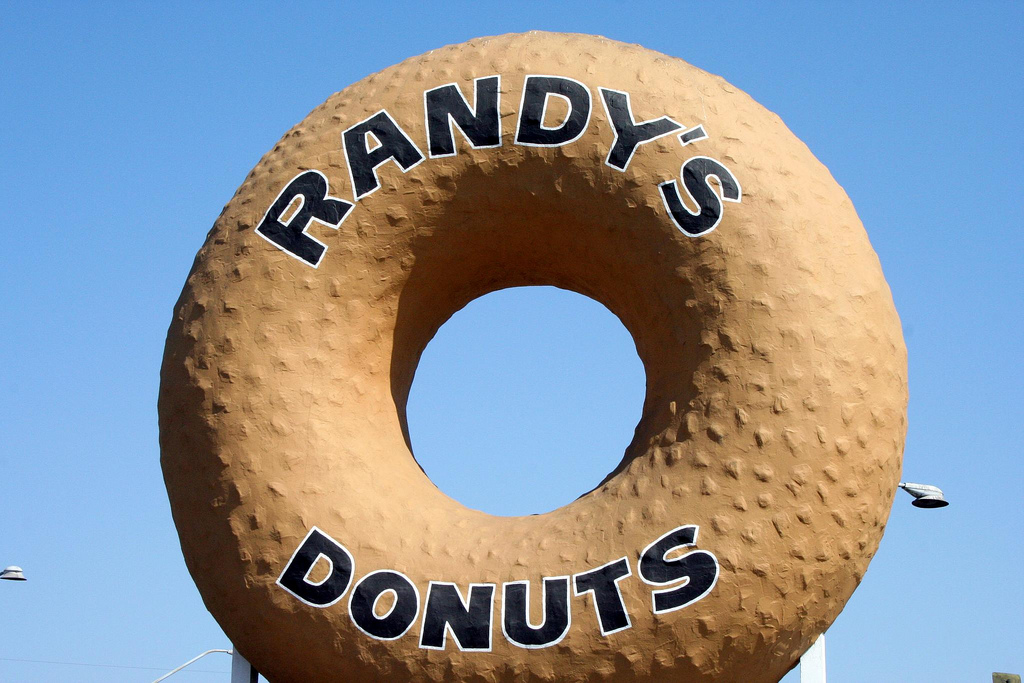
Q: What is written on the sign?
A: Randy's Donuts.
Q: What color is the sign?
A: Tan.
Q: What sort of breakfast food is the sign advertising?
A: Donuts.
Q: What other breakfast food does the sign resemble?
A: Bagels.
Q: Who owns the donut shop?
A: Randy.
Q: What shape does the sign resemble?
A: Circle.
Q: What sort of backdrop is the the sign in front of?
A: The sky.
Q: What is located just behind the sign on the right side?
A: A streetlight.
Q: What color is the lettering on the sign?
A: Black.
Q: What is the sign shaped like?
A: A donut.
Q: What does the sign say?
A: Randy's Donuts.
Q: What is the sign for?
A: A donut shop.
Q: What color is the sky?
A: Blue.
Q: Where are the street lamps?
A: Behind the donut sign.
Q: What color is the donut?
A: Brown.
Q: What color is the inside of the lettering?
A: Black.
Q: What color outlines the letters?
A: White.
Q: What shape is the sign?
A: A circle.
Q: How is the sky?
A: Cloudless.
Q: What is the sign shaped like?
A: A doughnut.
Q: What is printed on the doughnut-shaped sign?
A: "RANDY'S DONUTS".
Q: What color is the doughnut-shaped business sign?
A: Brown.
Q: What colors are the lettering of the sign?
A: Black and white.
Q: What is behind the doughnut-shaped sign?
A: Street lights.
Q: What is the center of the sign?
A: A hole.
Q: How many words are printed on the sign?
A: Two.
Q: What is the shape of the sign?
A: Doughnut.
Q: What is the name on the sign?
A: Randys donuts.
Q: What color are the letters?
A: Black.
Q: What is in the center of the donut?
A: A hole.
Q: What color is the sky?
A: Blue.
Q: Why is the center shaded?
A: Shadow.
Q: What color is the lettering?
A: Black and white.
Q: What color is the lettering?
A: Black and white.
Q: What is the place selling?
A: Donuts.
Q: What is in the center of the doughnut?
A: A doughnut hole.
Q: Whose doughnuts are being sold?
A: Randy's.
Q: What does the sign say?
A: Randy's donuts.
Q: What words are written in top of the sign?
A: Randy's.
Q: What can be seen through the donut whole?
A: The sky.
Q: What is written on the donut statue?
A: Randy's Donuts.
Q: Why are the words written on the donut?
A: To advertise the shop.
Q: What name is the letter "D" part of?
A: Randy's.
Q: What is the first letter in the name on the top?
A: The letter "R".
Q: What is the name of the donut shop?
A: Randy's Donuts.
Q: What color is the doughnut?
A: Brown.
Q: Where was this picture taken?
A: A doughnut shop.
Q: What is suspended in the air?
A: Doughnut sculpture.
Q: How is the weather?
A: Clear.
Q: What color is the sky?
A: Blue.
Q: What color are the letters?
A: Black.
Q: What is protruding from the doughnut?
A: A lamp post.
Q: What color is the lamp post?
A: White.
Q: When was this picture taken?
A: Morning.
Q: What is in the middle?
A: Hole.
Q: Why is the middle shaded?
A: Sun shadow.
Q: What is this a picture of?
A: Doughnut.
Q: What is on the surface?
A: Texture.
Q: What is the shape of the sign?
A: Doughnut.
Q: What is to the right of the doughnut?
A: Streetlight.